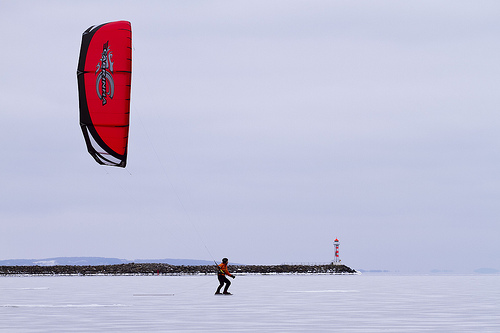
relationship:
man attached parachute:
[204, 253, 244, 298] [65, 14, 143, 171]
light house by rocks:
[330, 231, 342, 259] [7, 264, 358, 274]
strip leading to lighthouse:
[3, 254, 356, 281] [327, 234, 343, 266]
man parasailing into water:
[213, 258, 234, 296] [1, 275, 498, 331]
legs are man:
[213, 276, 231, 295] [213, 258, 234, 296]